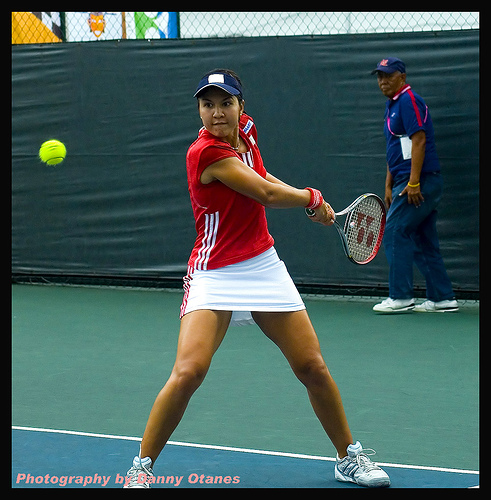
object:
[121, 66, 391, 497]
lady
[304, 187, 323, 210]
wristband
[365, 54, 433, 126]
tennis couch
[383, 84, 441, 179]
blue uniform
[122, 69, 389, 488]
woman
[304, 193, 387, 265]
racket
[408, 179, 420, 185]
wrist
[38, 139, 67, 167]
ball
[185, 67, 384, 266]
planes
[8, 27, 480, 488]
court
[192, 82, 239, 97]
visor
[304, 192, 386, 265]
tennis racket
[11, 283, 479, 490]
ground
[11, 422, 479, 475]
markings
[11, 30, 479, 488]
tennis court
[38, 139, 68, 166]
tennis ball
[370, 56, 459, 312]
man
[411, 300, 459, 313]
shoe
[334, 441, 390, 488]
shoe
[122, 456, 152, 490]
shoe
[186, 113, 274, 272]
shirt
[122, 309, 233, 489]
leg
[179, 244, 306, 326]
tennis skirt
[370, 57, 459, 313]
coach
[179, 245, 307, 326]
skirt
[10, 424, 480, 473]
line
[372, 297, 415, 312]
shoe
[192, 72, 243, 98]
cap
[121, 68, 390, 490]
player